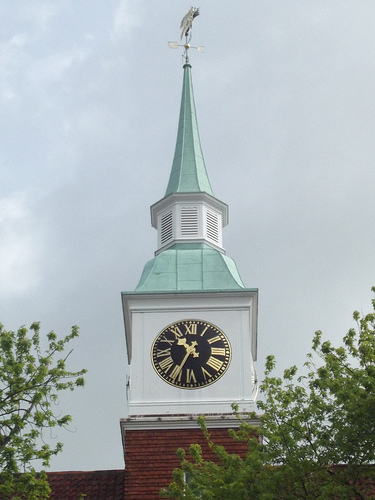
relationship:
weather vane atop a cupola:
[170, 3, 202, 64] [131, 243, 247, 292]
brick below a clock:
[0, 429, 373, 498] [153, 320, 229, 387]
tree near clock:
[147, 291, 373, 499] [153, 320, 229, 387]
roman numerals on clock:
[180, 319, 197, 338] [153, 320, 229, 387]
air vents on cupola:
[157, 206, 220, 246] [131, 243, 247, 292]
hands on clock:
[169, 337, 198, 381] [153, 320, 229, 387]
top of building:
[118, 1, 260, 451] [3, 432, 372, 499]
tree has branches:
[147, 291, 373, 499] [266, 407, 371, 498]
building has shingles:
[3, 432, 372, 499] [131, 243, 247, 292]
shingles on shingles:
[131, 243, 247, 292] [131, 243, 247, 292]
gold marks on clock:
[204, 323, 220, 334] [153, 320, 229, 387]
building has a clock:
[3, 432, 372, 499] [153, 320, 229, 387]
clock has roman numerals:
[153, 320, 229, 387] [180, 319, 197, 338]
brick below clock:
[0, 429, 373, 498] [153, 320, 229, 387]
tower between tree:
[120, 9, 263, 499] [183, 302, 373, 499]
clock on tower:
[153, 320, 229, 387] [120, 9, 263, 499]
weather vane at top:
[170, 3, 202, 64] [118, 1, 260, 451]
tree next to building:
[147, 291, 373, 499] [3, 432, 372, 499]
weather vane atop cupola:
[166, 0, 206, 64] [131, 243, 247, 292]